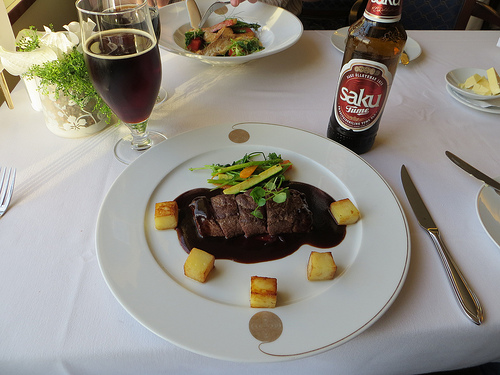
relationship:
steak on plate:
[194, 186, 314, 238] [97, 125, 412, 365]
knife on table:
[401, 163, 485, 325] [1, 31, 500, 375]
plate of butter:
[447, 68, 499, 103] [464, 68, 497, 94]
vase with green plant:
[25, 76, 110, 137] [21, 24, 110, 120]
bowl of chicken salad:
[157, 1, 305, 65] [183, 19, 264, 55]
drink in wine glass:
[85, 30, 162, 121] [74, 1, 167, 164]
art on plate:
[249, 312, 284, 343] [97, 125, 412, 365]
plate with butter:
[447, 68, 499, 103] [464, 68, 497, 94]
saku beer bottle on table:
[327, 0, 408, 154] [1, 31, 500, 375]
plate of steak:
[97, 125, 412, 365] [194, 186, 314, 238]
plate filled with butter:
[447, 68, 499, 103] [464, 68, 497, 94]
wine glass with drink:
[74, 1, 167, 164] [85, 30, 162, 121]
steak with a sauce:
[194, 186, 314, 238] [174, 182, 347, 265]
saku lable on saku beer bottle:
[334, 58, 392, 131] [327, 0, 408, 154]